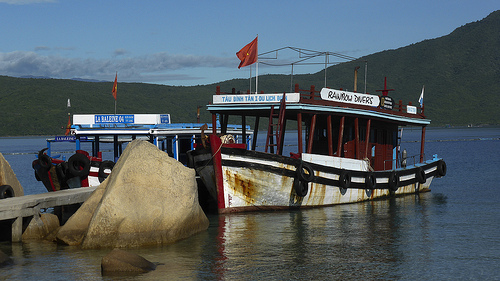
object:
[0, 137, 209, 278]
rocks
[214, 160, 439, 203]
stains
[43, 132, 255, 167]
area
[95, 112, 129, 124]
writing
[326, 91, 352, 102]
words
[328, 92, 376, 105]
rainbow divers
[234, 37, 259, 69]
flag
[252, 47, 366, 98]
frame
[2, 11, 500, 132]
terrain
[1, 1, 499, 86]
sky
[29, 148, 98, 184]
tires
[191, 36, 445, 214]
boat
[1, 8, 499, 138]
mountains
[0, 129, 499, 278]
water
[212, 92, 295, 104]
sign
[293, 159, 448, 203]
life preservers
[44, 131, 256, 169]
shore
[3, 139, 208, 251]
docks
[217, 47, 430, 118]
gazebo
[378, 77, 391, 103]
ladder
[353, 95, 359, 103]
letter